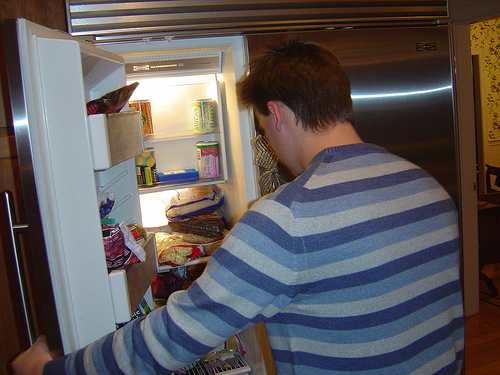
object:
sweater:
[28, 142, 463, 374]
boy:
[4, 40, 466, 374]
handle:
[3, 191, 57, 347]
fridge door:
[1, 16, 269, 375]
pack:
[87, 81, 141, 116]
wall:
[471, 18, 499, 146]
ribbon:
[252, 135, 290, 200]